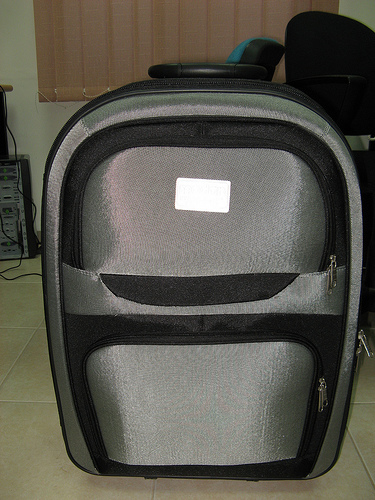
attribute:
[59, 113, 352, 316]
pocket — upper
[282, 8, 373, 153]
chair — BLACK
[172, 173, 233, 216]
sticker — WHTE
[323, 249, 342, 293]
zipper pulls — pair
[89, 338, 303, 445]
patch — silver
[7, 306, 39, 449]
tile — FLOOR, CLEAN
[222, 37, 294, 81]
chair — blue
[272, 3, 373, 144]
chair — BLACK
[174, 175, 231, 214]
patch — white, square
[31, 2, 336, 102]
blinds — TAN, FABRIC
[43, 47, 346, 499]
luggage — SILVER, BLACK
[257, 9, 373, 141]
chair — BLACK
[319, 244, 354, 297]
metal zipper — BLACK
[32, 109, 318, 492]
luggage — SILVER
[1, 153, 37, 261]
electronics — black , gray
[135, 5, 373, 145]
chairs — office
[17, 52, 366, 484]
luggage — BLACK, SILVER, grey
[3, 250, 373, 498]
floor — white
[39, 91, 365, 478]
suitcase — black 